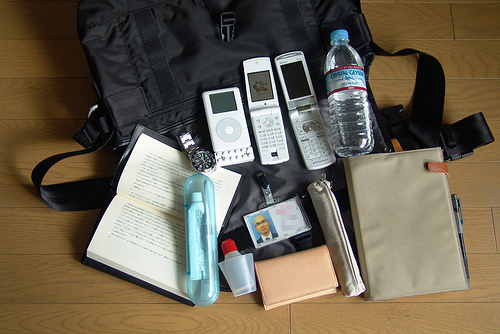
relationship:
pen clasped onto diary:
[435, 203, 474, 268] [348, 145, 469, 306]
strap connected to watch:
[175, 132, 198, 151] [171, 134, 218, 176]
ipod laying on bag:
[198, 94, 260, 184] [68, 5, 403, 128]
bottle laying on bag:
[324, 26, 379, 157] [72, 3, 496, 198]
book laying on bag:
[86, 131, 249, 300] [78, 4, 423, 268]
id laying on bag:
[236, 187, 319, 256] [30, 2, 493, 293]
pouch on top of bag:
[307, 179, 366, 296] [30, 2, 493, 293]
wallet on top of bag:
[252, 243, 342, 311] [30, 2, 493, 293]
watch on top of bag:
[171, 134, 218, 176] [60, 0, 426, 165]